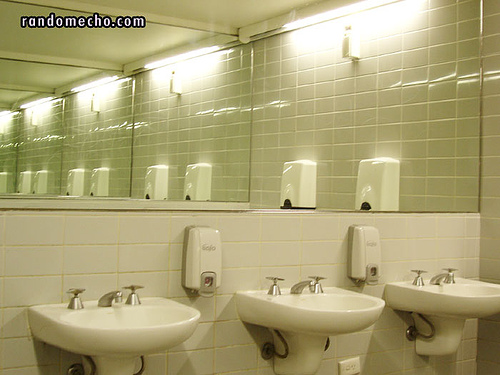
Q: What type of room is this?
A: A bathroom.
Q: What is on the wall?
A: A large mirror.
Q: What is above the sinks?
A: Mirror.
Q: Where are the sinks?
A: Under the mirror.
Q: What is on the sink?
A: Faucets.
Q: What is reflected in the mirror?
A: Lights.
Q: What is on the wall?
A: Tile.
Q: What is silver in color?
A: Pipes.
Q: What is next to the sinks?
A: Soap dispensers.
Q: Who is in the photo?
A: No people.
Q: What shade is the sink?
A: White.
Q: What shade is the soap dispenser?
A: White.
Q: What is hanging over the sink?
A: Large mirror.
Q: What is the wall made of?
A: Tiles.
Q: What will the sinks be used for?
A: Hand washing.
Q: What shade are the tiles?
A: White.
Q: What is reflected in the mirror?
A: Hand dryers.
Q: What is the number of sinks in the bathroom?
A: Three.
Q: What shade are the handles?
A: Silver.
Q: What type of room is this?
A: Bathroom.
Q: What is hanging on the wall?
A: Mirror.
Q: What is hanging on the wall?
A: Soap dispenser.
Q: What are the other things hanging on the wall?
A: Sinks.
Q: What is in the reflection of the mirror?
A: Hand dryers.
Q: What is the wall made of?
A: Tile.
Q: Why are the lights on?
A: So it is not dark.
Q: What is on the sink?
A: Faucet.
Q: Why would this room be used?
A: To wash hands.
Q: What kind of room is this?
A: Bathroom.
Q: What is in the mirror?
A: Reflection of soap dispensers.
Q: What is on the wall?
A: A mirror.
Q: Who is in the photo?
A: Nobody.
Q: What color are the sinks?
A: White.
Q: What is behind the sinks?
A: Tile.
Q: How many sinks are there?
A: Three.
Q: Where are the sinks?
A: Below the mirror.